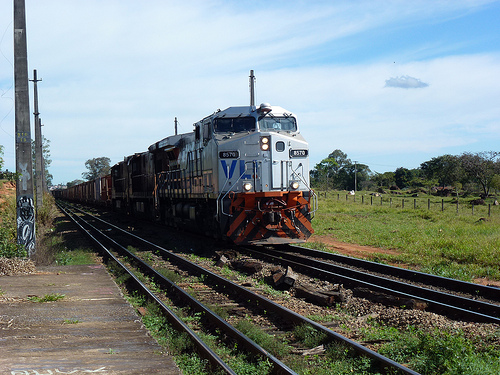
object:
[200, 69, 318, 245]
front end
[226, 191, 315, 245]
stripes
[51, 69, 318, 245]
car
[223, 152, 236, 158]
writing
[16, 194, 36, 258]
graffitti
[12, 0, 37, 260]
pole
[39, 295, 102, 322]
cement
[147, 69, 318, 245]
caboose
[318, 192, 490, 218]
fencing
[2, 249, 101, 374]
platform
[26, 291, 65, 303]
weeds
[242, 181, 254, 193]
lights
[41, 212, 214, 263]
shadow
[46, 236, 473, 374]
ground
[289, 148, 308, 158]
number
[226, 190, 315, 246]
bumper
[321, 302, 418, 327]
dirt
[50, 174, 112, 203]
cargo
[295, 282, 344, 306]
wood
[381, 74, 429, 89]
cloud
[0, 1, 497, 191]
sky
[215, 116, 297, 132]
window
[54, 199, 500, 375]
track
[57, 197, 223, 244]
bottom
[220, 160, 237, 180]
letter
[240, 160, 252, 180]
letter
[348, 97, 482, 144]
cloud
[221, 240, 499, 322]
lines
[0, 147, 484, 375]
rural area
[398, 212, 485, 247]
field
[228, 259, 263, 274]
wood